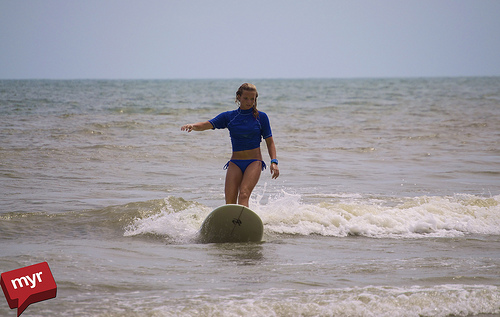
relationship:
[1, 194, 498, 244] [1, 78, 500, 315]
wave inside of water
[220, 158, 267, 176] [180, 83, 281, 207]
bikini bottom worn on surfer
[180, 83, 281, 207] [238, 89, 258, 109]
surfer has face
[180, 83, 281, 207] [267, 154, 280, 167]
surfer has wrist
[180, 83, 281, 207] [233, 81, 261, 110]
surfer has head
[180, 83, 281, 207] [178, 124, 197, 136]
surfer has hand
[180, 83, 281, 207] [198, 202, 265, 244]
surfer on top of surfboard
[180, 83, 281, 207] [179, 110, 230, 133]
surfer has arm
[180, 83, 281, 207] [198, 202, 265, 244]
surfer standing on surfboard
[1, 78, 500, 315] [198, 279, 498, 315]
water has bubbles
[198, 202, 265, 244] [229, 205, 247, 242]
surfboard has string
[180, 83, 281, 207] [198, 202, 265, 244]
surfer balancing on surfboard